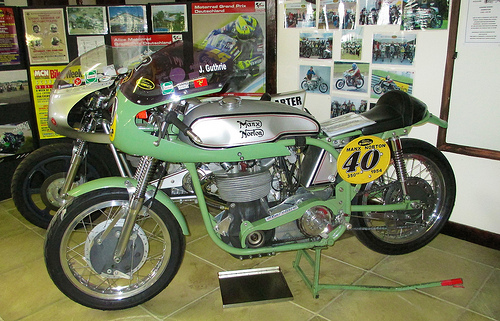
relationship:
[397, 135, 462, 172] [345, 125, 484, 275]
rim of wheel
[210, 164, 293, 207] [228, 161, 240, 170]
tank has lid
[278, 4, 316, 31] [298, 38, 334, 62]
picture of motorbikes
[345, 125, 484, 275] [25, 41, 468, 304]
wheel of bike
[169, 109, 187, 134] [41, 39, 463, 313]
gear of motorcycle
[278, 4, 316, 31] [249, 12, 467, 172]
picture on wall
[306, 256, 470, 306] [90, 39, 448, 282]
stand for motorcycle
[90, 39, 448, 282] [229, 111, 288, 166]
motorcycle has writing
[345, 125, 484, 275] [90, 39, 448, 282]
wheel of motorcycle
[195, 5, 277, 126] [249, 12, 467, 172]
sign on wall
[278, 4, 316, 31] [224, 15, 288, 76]
picture of person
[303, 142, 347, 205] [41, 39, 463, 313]
engine on motorcycle